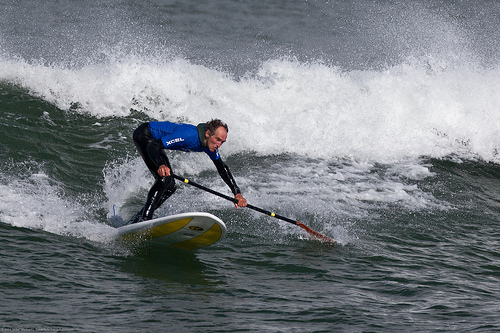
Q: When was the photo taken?
A: Daytime.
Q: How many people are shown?
A: One.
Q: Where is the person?
A: Water.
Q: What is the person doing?
A: Surfing.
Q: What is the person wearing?
A: Wetsuit.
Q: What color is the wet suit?
A: Black and blue.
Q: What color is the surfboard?
A: Yellow and white.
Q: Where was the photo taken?
A: Water.